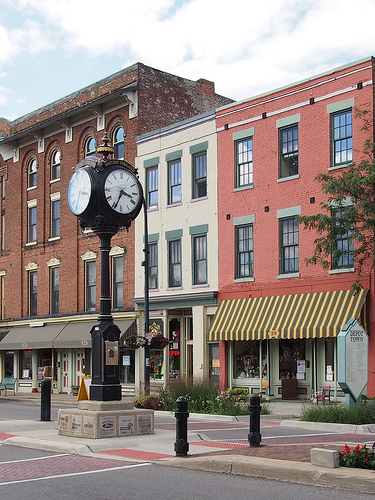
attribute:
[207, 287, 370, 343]
awning — green, yellow, striped, long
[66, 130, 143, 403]
clock — big, circular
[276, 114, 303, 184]
window — open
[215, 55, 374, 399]
building — red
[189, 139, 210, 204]
window — open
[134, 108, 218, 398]
building — white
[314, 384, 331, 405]
chair — blue, red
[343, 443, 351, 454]
flower — red, small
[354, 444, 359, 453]
flower — red, small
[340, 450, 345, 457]
flower — red, small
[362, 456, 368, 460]
flower — red, small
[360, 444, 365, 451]
flower — red, small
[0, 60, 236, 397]
building — brown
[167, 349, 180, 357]
sign — red, glowing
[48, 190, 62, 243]
window — white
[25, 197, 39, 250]
window — white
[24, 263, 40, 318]
window — white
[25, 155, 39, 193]
window — white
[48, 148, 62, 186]
window — white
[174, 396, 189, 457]
pole — short, black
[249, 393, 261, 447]
pole — short, black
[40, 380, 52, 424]
pole — short, black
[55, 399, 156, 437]
base — stone, grey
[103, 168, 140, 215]
clock face — white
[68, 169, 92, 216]
clock face — white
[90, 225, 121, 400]
pole — metal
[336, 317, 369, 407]
sign — large, blue, white, grey, green, metal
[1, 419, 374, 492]
pavement — red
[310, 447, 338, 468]
block — grey, small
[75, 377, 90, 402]
triangle — yellow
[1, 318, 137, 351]
awning — brown